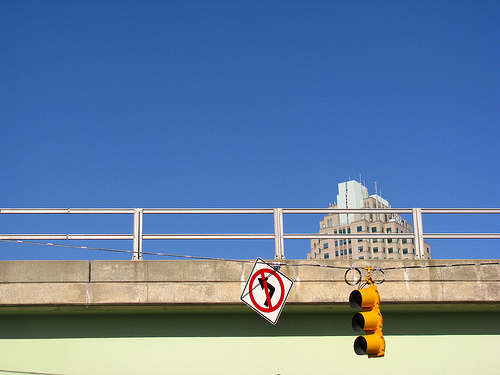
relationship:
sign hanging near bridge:
[240, 256, 294, 325] [0, 207, 499, 373]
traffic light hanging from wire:
[349, 267, 386, 358] [1, 237, 500, 270]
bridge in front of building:
[0, 207, 499, 373] [307, 173, 432, 260]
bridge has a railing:
[0, 207, 499, 373] [0, 207, 499, 259]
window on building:
[323, 241, 330, 249] [307, 173, 432, 260]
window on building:
[356, 225, 364, 233] [307, 173, 432, 260]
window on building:
[372, 226, 378, 233] [307, 173, 432, 260]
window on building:
[323, 253, 329, 259] [307, 173, 432, 260]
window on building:
[373, 246, 379, 253] [307, 173, 432, 260]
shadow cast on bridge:
[1, 310, 499, 373] [0, 207, 499, 373]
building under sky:
[307, 173, 432, 260] [1, 0, 499, 261]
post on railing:
[132, 210, 143, 262] [0, 207, 499, 259]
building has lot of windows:
[307, 173, 432, 260] [306, 197, 431, 258]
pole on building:
[374, 179, 378, 195] [307, 173, 432, 260]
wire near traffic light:
[344, 267, 362, 285] [349, 267, 386, 358]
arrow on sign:
[258, 277, 275, 306] [240, 256, 294, 325]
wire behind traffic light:
[370, 269, 386, 285] [349, 267, 386, 358]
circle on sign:
[248, 269, 286, 314] [240, 256, 294, 325]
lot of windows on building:
[306, 197, 431, 258] [307, 173, 432, 260]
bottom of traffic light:
[354, 332, 379, 354] [349, 267, 386, 358]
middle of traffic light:
[352, 311, 377, 331] [349, 267, 386, 358]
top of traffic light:
[350, 289, 374, 308] [349, 267, 386, 358]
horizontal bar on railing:
[1, 207, 500, 215] [0, 207, 499, 259]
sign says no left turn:
[240, 256, 294, 325] [249, 269, 285, 313]